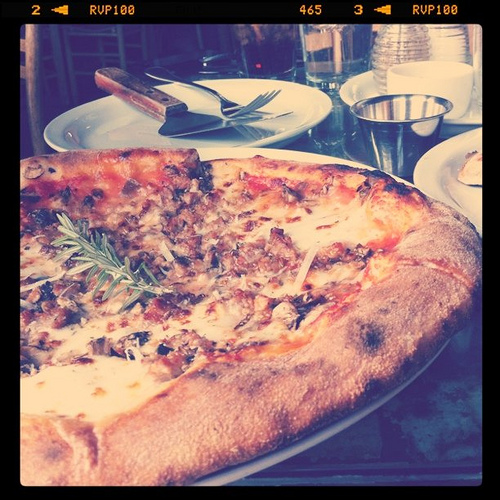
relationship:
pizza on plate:
[14, 143, 481, 496] [83, 151, 481, 484]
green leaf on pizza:
[54, 206, 176, 301] [14, 143, 481, 496]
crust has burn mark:
[254, 260, 481, 452] [346, 318, 397, 365]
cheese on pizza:
[35, 360, 145, 414] [14, 143, 481, 496]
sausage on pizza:
[174, 207, 293, 286] [14, 143, 481, 496]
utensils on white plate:
[89, 51, 281, 137] [45, 62, 331, 150]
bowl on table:
[360, 90, 454, 176] [24, 47, 479, 468]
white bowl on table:
[393, 55, 476, 125] [24, 47, 479, 468]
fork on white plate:
[144, 69, 299, 122] [45, 62, 331, 150]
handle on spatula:
[86, 61, 192, 114] [86, 65, 265, 140]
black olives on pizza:
[115, 326, 183, 368] [14, 143, 481, 496]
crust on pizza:
[254, 260, 481, 452] [14, 143, 481, 496]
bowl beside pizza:
[360, 90, 454, 176] [14, 143, 481, 496]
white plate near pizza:
[45, 62, 331, 150] [14, 143, 481, 496]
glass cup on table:
[291, 21, 367, 89] [24, 47, 479, 468]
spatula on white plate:
[86, 65, 265, 140] [45, 62, 331, 150]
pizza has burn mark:
[14, 143, 481, 496] [346, 318, 397, 365]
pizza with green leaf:
[14, 143, 481, 496] [54, 206, 176, 301]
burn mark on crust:
[346, 318, 397, 365] [254, 260, 481, 452]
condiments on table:
[180, 13, 294, 75] [24, 47, 479, 468]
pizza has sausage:
[14, 143, 481, 496] [174, 207, 293, 286]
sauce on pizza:
[36, 153, 161, 212] [14, 143, 481, 496]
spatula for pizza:
[86, 65, 265, 140] [14, 143, 481, 496]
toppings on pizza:
[28, 158, 210, 346] [14, 143, 481, 496]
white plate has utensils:
[45, 62, 331, 150] [89, 51, 281, 137]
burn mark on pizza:
[346, 318, 397, 365] [14, 143, 481, 496]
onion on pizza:
[295, 227, 336, 294] [14, 143, 481, 496]